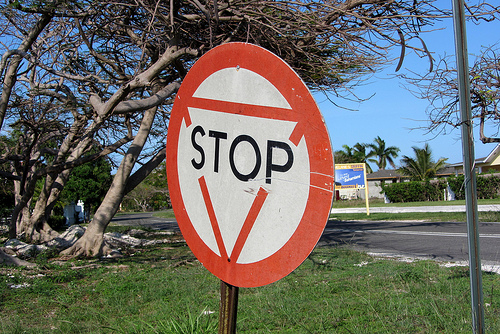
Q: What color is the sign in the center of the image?
A: Red, white, and black.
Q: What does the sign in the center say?
A: Stop.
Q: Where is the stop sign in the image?
A: In center.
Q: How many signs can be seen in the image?
A: Two.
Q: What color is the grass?
A: Green.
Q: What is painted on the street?
A: White lines.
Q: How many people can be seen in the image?
A: None.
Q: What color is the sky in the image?
A: Blue.